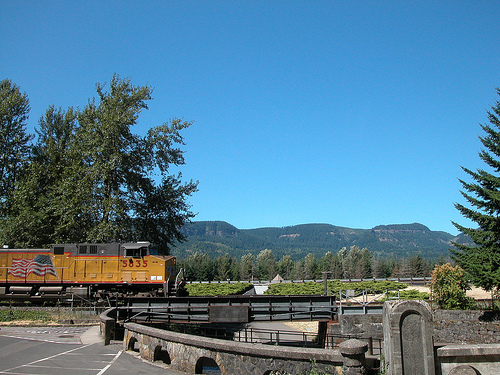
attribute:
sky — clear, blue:
[194, 33, 352, 127]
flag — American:
[19, 243, 103, 304]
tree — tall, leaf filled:
[23, 70, 205, 249]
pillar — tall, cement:
[377, 298, 447, 372]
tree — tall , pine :
[410, 77, 499, 314]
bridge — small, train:
[132, 291, 340, 332]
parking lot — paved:
[4, 316, 127, 373]